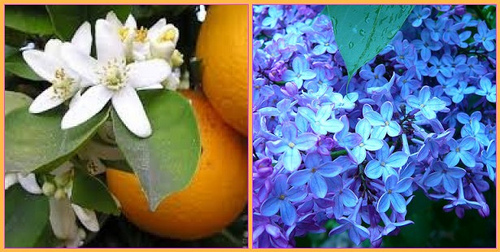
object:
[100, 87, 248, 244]
orange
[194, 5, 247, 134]
orange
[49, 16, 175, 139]
flower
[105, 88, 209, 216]
leaf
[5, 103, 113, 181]
leaf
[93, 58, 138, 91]
center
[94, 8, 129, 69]
petal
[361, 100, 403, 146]
flower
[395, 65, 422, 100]
flower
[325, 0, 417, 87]
leaf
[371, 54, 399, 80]
spot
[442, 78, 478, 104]
flower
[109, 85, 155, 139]
petal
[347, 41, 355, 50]
drops